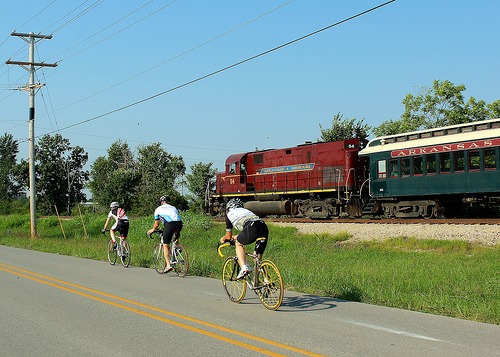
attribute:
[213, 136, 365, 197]
train engine — red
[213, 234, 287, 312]
bike — yellow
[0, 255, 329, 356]
lines — yellow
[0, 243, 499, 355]
road — paved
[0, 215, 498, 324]
grass — green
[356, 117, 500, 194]
train car — green, white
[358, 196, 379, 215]
stairs — metal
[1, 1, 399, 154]
powerlines — crossed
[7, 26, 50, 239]
telephone pole — tall, wood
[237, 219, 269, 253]
shorts — black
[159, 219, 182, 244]
shorts — black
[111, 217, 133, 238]
shorts — black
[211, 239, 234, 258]
handlebar — yellow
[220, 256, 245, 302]
rim — yellow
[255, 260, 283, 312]
rim — yellow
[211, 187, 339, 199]
stripe — yellow